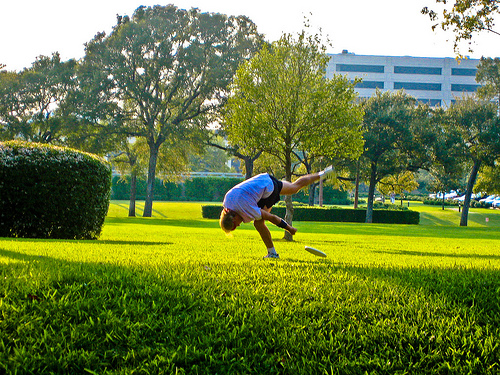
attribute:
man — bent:
[218, 161, 339, 261]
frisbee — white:
[304, 243, 329, 262]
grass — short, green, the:
[0, 199, 499, 272]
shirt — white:
[221, 173, 275, 223]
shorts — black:
[259, 166, 284, 210]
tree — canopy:
[223, 12, 367, 241]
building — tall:
[318, 49, 499, 189]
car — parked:
[476, 192, 499, 207]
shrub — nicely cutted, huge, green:
[1, 137, 115, 248]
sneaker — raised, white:
[324, 161, 340, 183]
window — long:
[333, 63, 387, 75]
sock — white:
[316, 169, 328, 185]